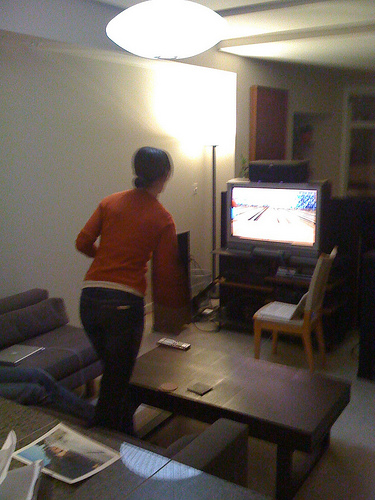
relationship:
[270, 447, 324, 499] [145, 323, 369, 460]
stand of table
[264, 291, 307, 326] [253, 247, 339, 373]
laptop on seat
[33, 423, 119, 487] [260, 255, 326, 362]
photo on seat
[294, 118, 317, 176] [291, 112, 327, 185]
someone in door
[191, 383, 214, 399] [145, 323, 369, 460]
remote control on table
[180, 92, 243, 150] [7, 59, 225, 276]
light reflected on board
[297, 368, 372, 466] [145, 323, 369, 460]
edge of table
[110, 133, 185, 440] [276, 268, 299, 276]
woman playing wii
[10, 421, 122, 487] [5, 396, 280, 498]
photo on counter